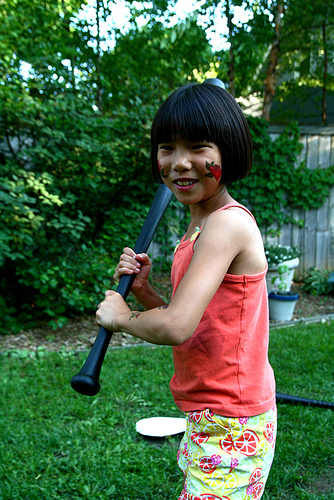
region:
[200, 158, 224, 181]
A flower painted on the cheek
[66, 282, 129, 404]
A hand holding a bat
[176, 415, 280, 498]
Colorful yellow shorts with watermelon design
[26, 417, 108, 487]
Green lush grass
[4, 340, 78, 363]
Green leaves on the grown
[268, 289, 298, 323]
A white flower pot with blue trim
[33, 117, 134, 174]
leaves on a tree top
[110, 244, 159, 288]
fingers around a bat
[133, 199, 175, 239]
A black bat with a green background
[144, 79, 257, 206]
A young girl with black hair, smiling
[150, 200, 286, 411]
salmon coloured spaghetti strap tank top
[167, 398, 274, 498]
yellow shorts with citrus fruit pattern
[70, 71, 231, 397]
black plastic base ball bat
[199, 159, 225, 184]
rose tattoo on girl's cheek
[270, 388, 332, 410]
black plastic base ball bat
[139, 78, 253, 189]
jet black short hair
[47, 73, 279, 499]
small girl playing base ball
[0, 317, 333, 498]
beautiful green grassy lawn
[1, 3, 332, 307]
grouping of green leafy planst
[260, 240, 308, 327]
two terra cotta plant pots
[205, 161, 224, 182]
flower tattoo on face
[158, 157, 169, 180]
flower tattoo on right cheek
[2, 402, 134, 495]
green grass on ground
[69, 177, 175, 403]
black baseball bat in hand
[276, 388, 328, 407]
baseball bat on the ground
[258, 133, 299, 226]
leaves in the yard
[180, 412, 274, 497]
yellow shorts on girl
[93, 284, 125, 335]
left hand on girls arm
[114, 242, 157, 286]
right hand on girl's arm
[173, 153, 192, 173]
nose on the girl's face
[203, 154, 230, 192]
a tattoo on the girls face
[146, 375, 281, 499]
the girl is wearing bright pants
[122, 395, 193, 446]
there is a racket on the ground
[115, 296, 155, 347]
the girl has a tattoo on her arm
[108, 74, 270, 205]
the girl is chinese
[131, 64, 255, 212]
the girl is happy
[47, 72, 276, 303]
the girl is playing baseball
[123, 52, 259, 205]
the girl has black hair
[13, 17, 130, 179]
tall green trees in the background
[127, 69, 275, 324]
the girl is wearing an orange tank top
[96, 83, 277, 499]
young girl holding a bat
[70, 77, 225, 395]
black bat in girl's hands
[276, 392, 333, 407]
black bat on the ground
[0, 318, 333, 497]
green grass on the yard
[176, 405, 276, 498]
pair of yellow shorts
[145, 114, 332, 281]
wooden fence behind the girl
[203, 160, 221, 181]
drawing of a rose on girls face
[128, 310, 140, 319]
drawing of a rose on girl's arm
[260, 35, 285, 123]
brown tree trunk behind the fence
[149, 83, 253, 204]
face of a little girl smiling